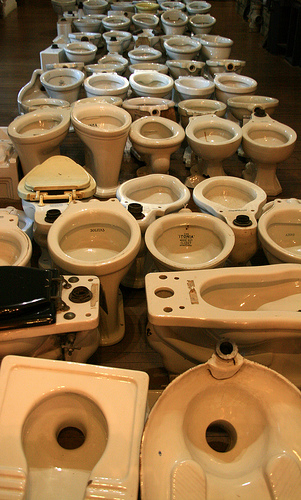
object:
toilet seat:
[23, 149, 92, 199]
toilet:
[144, 260, 300, 388]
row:
[8, 97, 291, 168]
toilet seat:
[2, 264, 57, 332]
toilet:
[0, 350, 150, 498]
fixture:
[45, 196, 143, 350]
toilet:
[133, 2, 161, 16]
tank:
[39, 42, 67, 73]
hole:
[178, 303, 184, 313]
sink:
[138, 336, 301, 500]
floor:
[230, 30, 300, 202]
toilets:
[71, 10, 101, 35]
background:
[0, 1, 301, 499]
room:
[0, 0, 301, 499]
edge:
[142, 269, 155, 322]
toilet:
[14, 153, 98, 248]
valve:
[160, 304, 206, 325]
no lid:
[200, 271, 299, 314]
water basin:
[17, 69, 66, 114]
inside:
[248, 290, 261, 311]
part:
[189, 318, 225, 329]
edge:
[282, 52, 300, 71]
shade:
[263, 1, 300, 73]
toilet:
[37, 63, 85, 105]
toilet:
[82, 69, 129, 99]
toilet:
[128, 65, 173, 98]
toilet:
[173, 72, 216, 101]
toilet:
[214, 70, 259, 102]